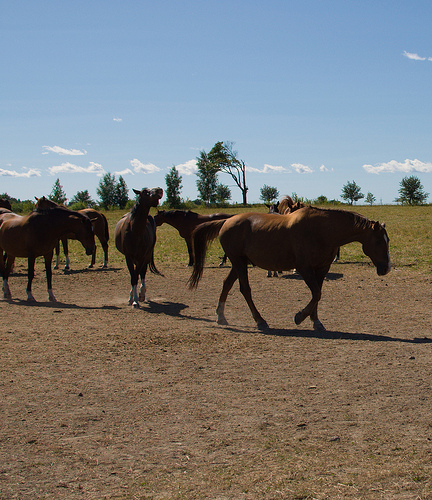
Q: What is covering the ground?
A: Dirt and grass.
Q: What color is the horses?
A: Brown.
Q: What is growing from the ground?
A: Trees and grass.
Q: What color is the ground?
A: Brown and green.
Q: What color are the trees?
A: Green.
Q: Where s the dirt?
A: On the ground.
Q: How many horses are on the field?
A: 6.